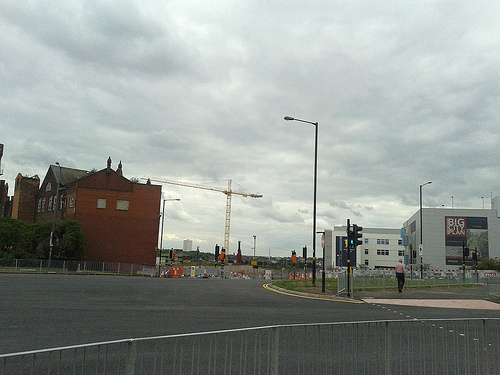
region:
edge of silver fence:
[230, 307, 389, 339]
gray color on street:
[72, 282, 228, 331]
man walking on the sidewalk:
[386, 254, 410, 292]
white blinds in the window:
[95, 194, 141, 217]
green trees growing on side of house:
[29, 211, 101, 268]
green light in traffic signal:
[331, 235, 371, 255]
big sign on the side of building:
[431, 205, 480, 248]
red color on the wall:
[89, 225, 148, 250]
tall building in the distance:
[177, 233, 199, 258]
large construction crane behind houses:
[185, 163, 258, 260]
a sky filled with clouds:
[1, 0, 498, 257]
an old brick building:
[6, 157, 166, 277]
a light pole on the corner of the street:
[281, 108, 322, 288]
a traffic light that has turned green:
[343, 213, 365, 303]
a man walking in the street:
[391, 255, 408, 294]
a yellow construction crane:
[136, 163, 268, 268]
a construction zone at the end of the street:
[158, 248, 321, 282]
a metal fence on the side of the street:
[0, 256, 160, 276]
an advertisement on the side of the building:
[443, 214, 492, 267]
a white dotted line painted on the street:
[361, 299, 498, 354]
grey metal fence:
[2, 313, 499, 372]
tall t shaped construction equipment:
[125, 158, 263, 264]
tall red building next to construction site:
[35, 158, 180, 270]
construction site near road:
[163, 180, 314, 282]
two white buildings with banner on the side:
[318, 210, 498, 286]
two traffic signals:
[341, 218, 372, 300]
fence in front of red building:
[6, 253, 166, 281]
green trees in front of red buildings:
[3, 213, 79, 260]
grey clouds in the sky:
[71, 31, 276, 134]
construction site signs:
[171, 245, 306, 277]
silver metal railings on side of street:
[272, 315, 499, 373]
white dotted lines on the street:
[373, 302, 412, 317]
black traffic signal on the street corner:
[345, 217, 361, 306]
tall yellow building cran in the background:
[141, 163, 263, 264]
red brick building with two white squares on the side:
[42, 159, 162, 278]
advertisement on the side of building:
[433, 213, 496, 268]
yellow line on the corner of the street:
[262, 281, 360, 307]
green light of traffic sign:
[348, 237, 355, 247]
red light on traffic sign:
[412, 249, 419, 257]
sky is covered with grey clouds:
[131, 114, 282, 166]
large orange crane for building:
[140, 174, 262, 264]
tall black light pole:
[280, 115, 319, 289]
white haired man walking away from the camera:
[392, 258, 407, 294]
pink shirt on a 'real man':
[393, 263, 406, 273]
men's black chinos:
[394, 272, 405, 291]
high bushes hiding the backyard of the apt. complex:
[0, 214, 85, 270]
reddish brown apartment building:
[0, 156, 163, 274]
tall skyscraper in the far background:
[181, 237, 193, 253]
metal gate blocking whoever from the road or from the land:
[0, 316, 499, 373]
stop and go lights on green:
[345, 215, 363, 296]